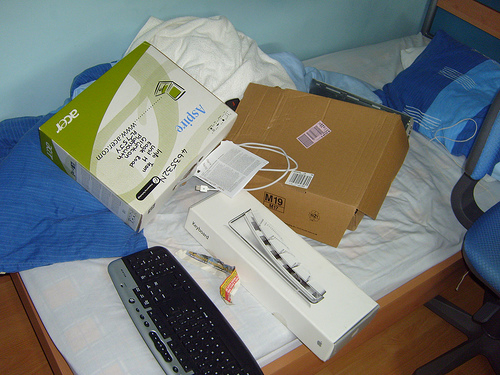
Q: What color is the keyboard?
A: Black.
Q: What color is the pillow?
A: Blue.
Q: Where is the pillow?
A: On the bed.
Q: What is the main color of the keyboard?
A: Black.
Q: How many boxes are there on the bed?
A: Three.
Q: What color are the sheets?
A: White.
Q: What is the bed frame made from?
A: Wood.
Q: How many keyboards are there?
A: One.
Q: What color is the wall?
A: Blue.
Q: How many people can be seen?
A: Zero.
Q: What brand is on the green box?
A: Acer.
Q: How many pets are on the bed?
A: Zero.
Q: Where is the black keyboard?
A: At the foot of the bed.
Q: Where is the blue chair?
A: Near the top of the bed.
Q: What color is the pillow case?
A: Blue.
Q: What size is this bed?
A: Twin.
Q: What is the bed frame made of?
A: Wood.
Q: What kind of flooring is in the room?
A: Wood.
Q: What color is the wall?
A: Light blue.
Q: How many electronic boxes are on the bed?
A: 3.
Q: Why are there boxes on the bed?
A: Electronics for the room.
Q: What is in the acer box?
A: Laptop computer.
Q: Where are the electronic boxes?
A: On the twin bed.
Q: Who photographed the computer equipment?
A: A young boy.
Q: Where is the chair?
A: Beside the bed.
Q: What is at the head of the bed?
A: Blue pillow.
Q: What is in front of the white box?
A: Black keyboard.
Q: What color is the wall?
A: Blue.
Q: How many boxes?
A: 3.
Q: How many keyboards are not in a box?
A: 1.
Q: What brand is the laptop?
A: Acer.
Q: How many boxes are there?
A: 3.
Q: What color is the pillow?
A: Blue.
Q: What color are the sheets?
A: White.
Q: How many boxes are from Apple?
A: 1.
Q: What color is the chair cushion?
A: Blue.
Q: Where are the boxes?
A: On the bed.